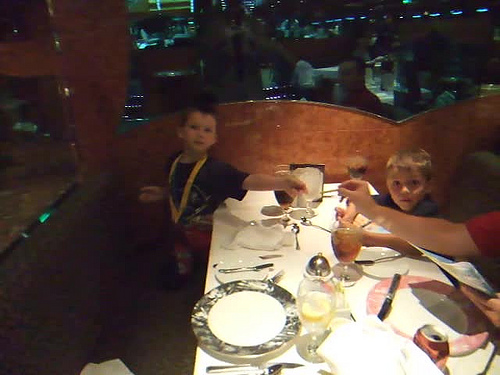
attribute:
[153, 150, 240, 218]
tee shirt — black, cotton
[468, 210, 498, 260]
sleeve — red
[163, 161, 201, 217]
lanyard — yellow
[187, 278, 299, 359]
plate — green, white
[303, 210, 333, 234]
spoon — silver, metal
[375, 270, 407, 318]
knife — metal, silver, butter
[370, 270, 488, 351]
plate — pink, white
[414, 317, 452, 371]
can — soda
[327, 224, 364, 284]
glass — drinking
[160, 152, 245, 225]
shirt — black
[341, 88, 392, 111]
shirt — red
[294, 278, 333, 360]
glass — wine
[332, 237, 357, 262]
tea — ice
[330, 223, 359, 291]
glass — wine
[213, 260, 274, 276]
knife — butter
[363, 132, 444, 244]
boy — blonde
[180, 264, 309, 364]
plate — white, decorated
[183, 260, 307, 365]
glass — clear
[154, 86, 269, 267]
boy — small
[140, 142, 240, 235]
shirt — black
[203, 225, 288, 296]
plate — white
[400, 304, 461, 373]
can — metal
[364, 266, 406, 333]
knife — silver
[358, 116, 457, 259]
boy — young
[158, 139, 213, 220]
strap — yellow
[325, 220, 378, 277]
glass — short